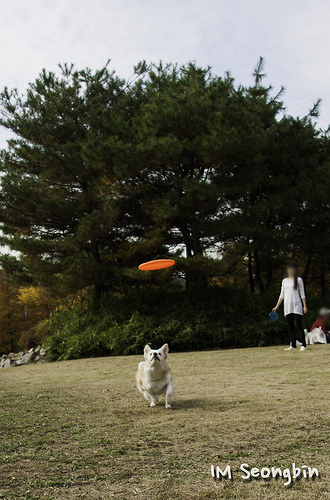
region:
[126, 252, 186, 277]
a red frisbee in the air.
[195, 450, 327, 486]
a watermark on a picture.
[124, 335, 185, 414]
a dog running in a field.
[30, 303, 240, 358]
a bunch of green bushes.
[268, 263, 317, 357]
a woman standing with a blue frisbee.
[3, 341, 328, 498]
a field of brown grass.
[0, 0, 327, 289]
a cloudy blue sky.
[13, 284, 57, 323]
a yellow leaf filled tree.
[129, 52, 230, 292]
a tall green pine tree.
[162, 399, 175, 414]
a dog's front left paw.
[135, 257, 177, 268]
Orange Frisbee in the air.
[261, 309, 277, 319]
Blue frisbee in woman's hand.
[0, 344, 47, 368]
Pile of rocks on side of bushes.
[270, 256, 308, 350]
Woman holding blue frisbee.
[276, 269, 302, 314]
White top being worn by a woman.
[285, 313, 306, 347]
Black pants being worn a woman.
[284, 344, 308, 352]
White shoes being worn a woman.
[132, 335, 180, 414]
Dog about to jump for frisbee.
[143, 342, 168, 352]
Perky beige dog ears.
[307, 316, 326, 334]
Red blanket behind woman.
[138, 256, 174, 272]
a red plastic frisbee flying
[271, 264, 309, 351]
a woman with dark hair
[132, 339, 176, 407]
a little tan dog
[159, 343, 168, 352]
the tan ear of the dog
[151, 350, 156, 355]
the black nose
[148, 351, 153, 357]
the black eye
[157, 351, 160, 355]
the black eye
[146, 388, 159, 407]
the short tan leg of the dog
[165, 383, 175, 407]
the short tan leg of the dog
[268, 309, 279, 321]
a blue plastic frisbee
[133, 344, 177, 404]
this is a puppy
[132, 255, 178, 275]
this is a lid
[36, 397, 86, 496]
this is a grass area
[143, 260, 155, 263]
the lid is red in color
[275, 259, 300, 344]
this is a lady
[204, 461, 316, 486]
this is a writing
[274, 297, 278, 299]
the lady is light skinned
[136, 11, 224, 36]
this is the sky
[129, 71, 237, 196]
this is a tree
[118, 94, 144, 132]
the tree has green leaves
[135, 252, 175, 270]
Orange Frisbee in the air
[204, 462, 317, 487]
Signature of the person who took the picture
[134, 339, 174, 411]
Dog chasing orange frisbee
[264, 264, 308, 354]
Girl playing frisbee with a dog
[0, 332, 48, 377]
Rock wall in Park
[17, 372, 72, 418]
Trodden brown grass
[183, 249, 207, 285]
Trunk of evergreen tree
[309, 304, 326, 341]
People relaxing in the park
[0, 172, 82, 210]
Branches of evergreen tree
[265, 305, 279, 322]
Frisbee held in hand